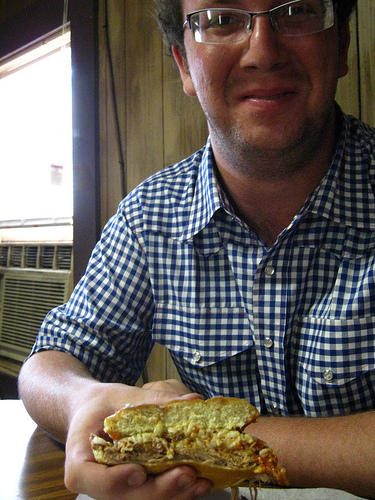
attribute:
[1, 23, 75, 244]
window — window unit style air 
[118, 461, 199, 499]
middle finger — middle 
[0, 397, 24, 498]
table — round brown wooden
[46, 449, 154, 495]
finger — index 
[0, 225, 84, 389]
a/c — old, dirty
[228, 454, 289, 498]
cheese —  dripping out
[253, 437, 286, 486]
tomato —  dripping out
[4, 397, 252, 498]
table — wooden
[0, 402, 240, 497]
table — wood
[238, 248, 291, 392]
buttons — white 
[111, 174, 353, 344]
shirt — blue , white 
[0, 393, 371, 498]
table top — wood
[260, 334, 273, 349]
button — white, pearl, snap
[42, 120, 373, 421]
shirt — Plaid , blue checkered button-down , plaid blue , white 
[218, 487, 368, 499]
white napkin — white 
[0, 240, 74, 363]
unit — air conditioning 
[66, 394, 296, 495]
sandwhich — pork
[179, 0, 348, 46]
eyeglasses — clear, black, plastic rimmed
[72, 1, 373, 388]
wall — wooden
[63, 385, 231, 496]
hand — man's right 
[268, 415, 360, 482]
arm — man's 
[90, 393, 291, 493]
hand —  man's right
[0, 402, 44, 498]
reflected — sunlight 